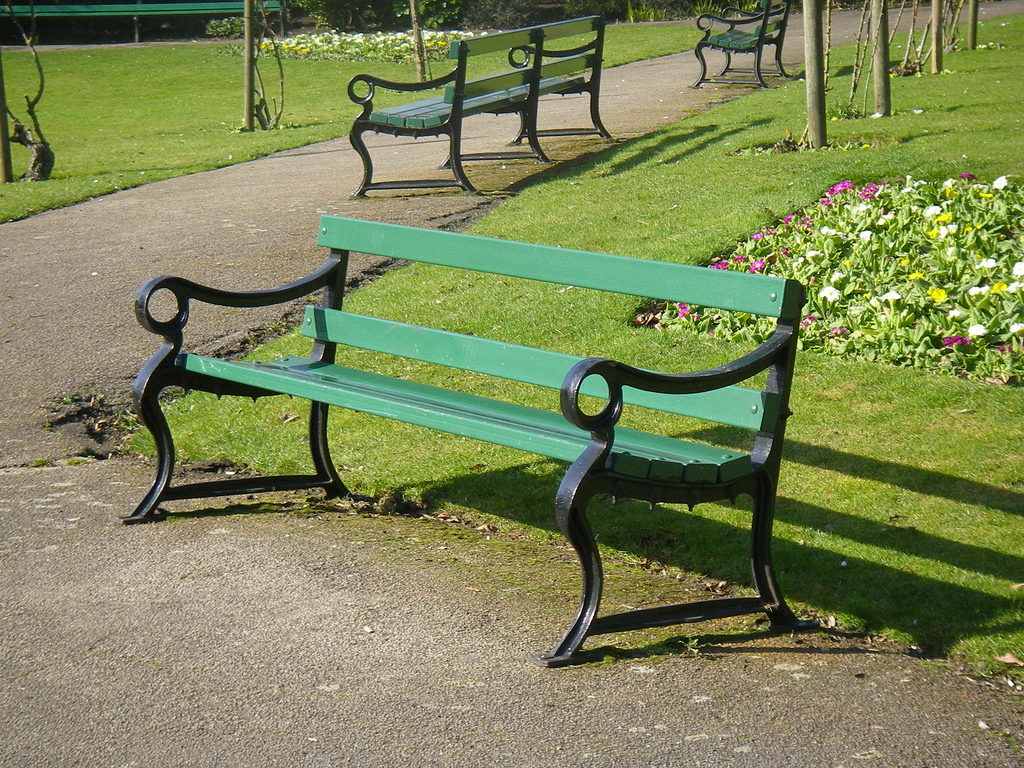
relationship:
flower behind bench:
[871, 288, 904, 318] [694, 0, 800, 87]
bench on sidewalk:
[135, 213, 825, 666] [0, 0, 1022, 766]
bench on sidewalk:
[350, 11, 613, 198] [0, 0, 1022, 766]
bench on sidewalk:
[689, 3, 797, 92] [0, 0, 1022, 766]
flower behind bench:
[818, 178, 857, 207] [135, 213, 825, 666]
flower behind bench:
[907, 336, 936, 360] [135, 213, 825, 666]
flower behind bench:
[819, 281, 854, 320] [135, 213, 825, 666]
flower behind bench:
[967, 247, 1006, 280] [135, 213, 825, 666]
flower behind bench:
[926, 219, 966, 249] [135, 213, 825, 666]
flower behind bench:
[939, 174, 966, 204] [135, 213, 825, 666]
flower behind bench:
[914, 199, 952, 228] [135, 213, 825, 666]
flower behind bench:
[958, 166, 981, 189] [135, 213, 825, 666]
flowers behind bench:
[939, 335, 971, 351] [109, 214, 819, 667]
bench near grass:
[348, 17, 619, 201] [131, 9, 1024, 679]